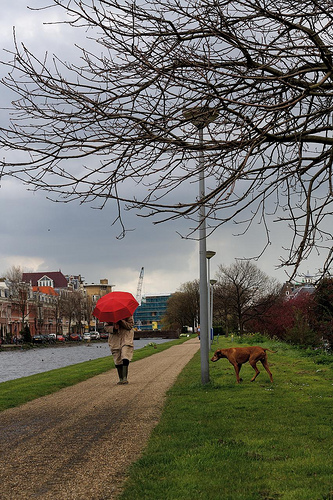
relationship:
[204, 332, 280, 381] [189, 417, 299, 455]
dog on grass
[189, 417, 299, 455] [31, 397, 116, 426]
grass alongside sidewalk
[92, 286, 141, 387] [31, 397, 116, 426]
man walking on sidewalk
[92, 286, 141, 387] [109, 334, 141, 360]
man wearing trenchcoat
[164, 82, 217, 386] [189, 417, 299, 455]
pole on top of grass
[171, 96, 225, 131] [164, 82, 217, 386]
light attached to pole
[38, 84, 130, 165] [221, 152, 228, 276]
branches attached to tree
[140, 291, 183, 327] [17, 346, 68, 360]
building on side of river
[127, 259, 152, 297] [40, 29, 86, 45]
crane in air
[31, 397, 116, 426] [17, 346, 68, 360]
sidewalk near river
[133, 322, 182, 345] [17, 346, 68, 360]
bridge over river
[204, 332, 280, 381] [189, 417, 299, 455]
dog on top of grass